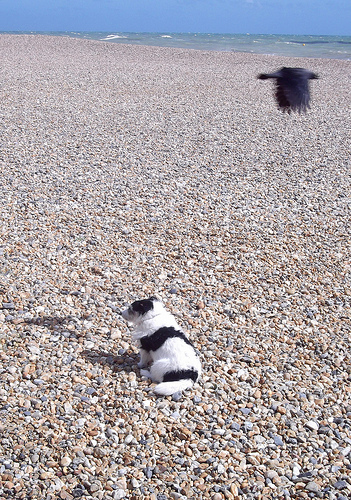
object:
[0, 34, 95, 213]
rocks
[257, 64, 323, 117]
bird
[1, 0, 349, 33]
sky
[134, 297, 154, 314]
ear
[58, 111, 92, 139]
rocks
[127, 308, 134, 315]
dog's eye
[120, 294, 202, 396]
black/white dog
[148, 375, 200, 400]
tail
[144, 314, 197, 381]
coat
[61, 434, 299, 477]
floor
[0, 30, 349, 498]
beach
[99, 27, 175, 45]
ripples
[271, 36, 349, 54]
ripples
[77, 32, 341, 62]
water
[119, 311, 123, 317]
nose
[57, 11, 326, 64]
sea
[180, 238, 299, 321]
stone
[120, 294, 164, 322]
head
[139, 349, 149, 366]
arm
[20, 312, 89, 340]
shadow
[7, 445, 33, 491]
pebbles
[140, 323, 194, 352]
black stripe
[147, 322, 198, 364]
dog's back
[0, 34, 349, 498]
ground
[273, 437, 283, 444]
pebble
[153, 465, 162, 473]
pebble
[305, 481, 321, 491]
pebble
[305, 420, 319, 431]
pebble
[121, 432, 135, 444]
pebble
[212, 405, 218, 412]
rocks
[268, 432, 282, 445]
rocks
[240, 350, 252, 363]
rocks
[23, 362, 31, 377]
rocks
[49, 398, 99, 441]
part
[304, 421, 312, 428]
part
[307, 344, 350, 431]
stone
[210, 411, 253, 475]
part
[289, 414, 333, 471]
part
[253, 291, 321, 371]
part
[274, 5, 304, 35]
air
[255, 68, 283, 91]
wings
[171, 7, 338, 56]
background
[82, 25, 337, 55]
body